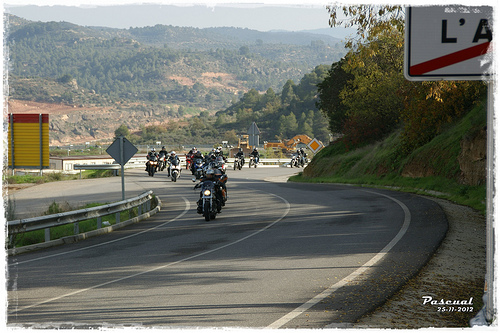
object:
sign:
[404, 6, 490, 79]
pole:
[481, 83, 497, 321]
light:
[204, 190, 210, 196]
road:
[5, 166, 449, 333]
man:
[195, 157, 228, 213]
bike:
[192, 163, 228, 222]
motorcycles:
[144, 153, 305, 221]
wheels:
[205, 202, 211, 222]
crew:
[145, 146, 308, 221]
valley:
[0, 0, 500, 333]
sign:
[5, 114, 48, 169]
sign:
[105, 134, 138, 166]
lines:
[261, 190, 411, 329]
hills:
[0, 14, 290, 110]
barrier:
[6, 190, 154, 249]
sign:
[307, 138, 323, 154]